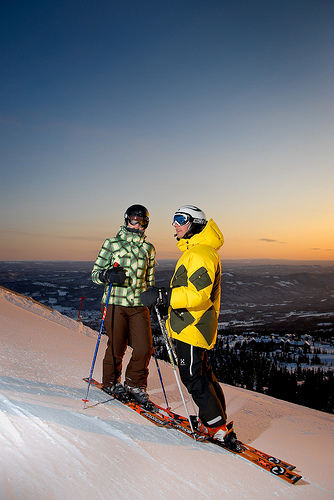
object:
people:
[139, 202, 231, 443]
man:
[138, 201, 235, 443]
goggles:
[125, 212, 150, 227]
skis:
[161, 408, 301, 484]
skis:
[82, 376, 171, 426]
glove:
[100, 267, 132, 286]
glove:
[140, 284, 175, 303]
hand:
[94, 263, 133, 285]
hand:
[138, 283, 176, 310]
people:
[91, 202, 156, 405]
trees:
[147, 307, 334, 415]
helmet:
[171, 203, 207, 241]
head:
[170, 204, 206, 240]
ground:
[0, 441, 93, 500]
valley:
[0, 253, 334, 500]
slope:
[0, 283, 332, 500]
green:
[119, 241, 123, 246]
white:
[112, 240, 120, 252]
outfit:
[90, 228, 155, 405]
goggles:
[170, 209, 189, 227]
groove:
[113, 417, 173, 484]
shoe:
[204, 423, 220, 437]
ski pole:
[82, 262, 122, 408]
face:
[171, 214, 192, 239]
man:
[91, 201, 159, 395]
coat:
[91, 227, 158, 310]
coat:
[164, 217, 226, 351]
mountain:
[0, 281, 334, 500]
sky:
[0, 0, 334, 260]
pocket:
[187, 267, 213, 292]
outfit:
[157, 217, 227, 426]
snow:
[10, 286, 331, 486]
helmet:
[123, 201, 151, 234]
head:
[122, 201, 151, 235]